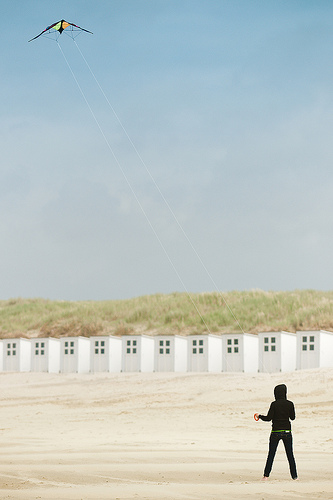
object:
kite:
[28, 18, 93, 43]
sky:
[1, 0, 330, 293]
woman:
[258, 383, 298, 481]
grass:
[1, 288, 332, 338]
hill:
[1, 288, 333, 334]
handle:
[253, 412, 262, 423]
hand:
[253, 412, 262, 419]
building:
[295, 328, 323, 372]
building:
[254, 330, 288, 375]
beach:
[0, 376, 332, 500]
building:
[220, 332, 248, 372]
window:
[224, 338, 240, 359]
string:
[56, 40, 261, 417]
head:
[273, 383, 288, 401]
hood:
[273, 384, 287, 401]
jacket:
[258, 384, 296, 430]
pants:
[263, 430, 298, 480]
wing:
[68, 23, 95, 36]